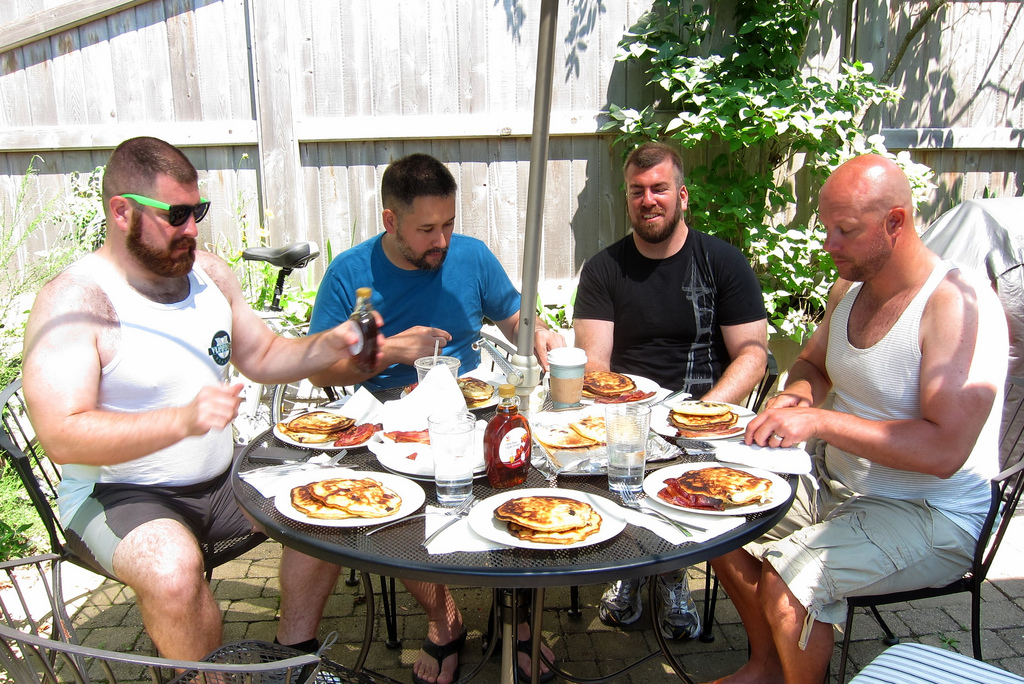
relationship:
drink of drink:
[605, 404, 651, 491] [609, 441, 644, 484]